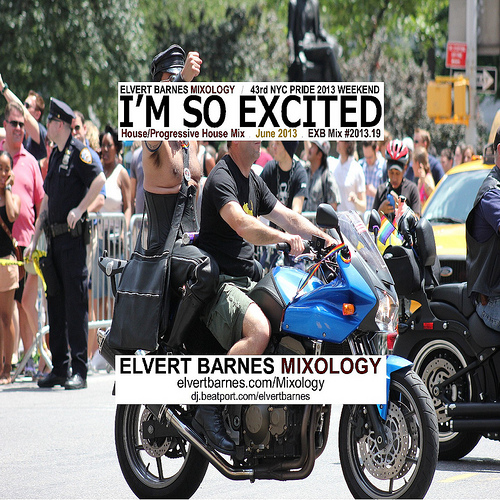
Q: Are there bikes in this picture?
A: Yes, there is a bike.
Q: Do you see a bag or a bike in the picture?
A: Yes, there is a bike.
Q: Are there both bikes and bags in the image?
A: Yes, there are both a bike and a bag.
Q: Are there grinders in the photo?
A: No, there are no grinders.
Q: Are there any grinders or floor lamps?
A: No, there are no grinders or floor lamps.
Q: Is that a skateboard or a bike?
A: That is a bike.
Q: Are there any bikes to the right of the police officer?
A: Yes, there is a bike to the right of the police officer.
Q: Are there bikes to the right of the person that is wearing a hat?
A: Yes, there is a bike to the right of the police officer.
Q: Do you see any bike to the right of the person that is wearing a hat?
A: Yes, there is a bike to the right of the police officer.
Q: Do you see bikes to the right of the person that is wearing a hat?
A: Yes, there is a bike to the right of the police officer.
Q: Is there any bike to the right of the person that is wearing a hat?
A: Yes, there is a bike to the right of the police officer.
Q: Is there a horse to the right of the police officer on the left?
A: No, there is a bike to the right of the police officer.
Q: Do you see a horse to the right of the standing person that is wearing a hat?
A: No, there is a bike to the right of the police officer.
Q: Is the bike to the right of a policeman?
A: Yes, the bike is to the right of a policeman.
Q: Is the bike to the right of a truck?
A: No, the bike is to the right of a policeman.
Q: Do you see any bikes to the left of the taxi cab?
A: Yes, there is a bike to the left of the taxi cab.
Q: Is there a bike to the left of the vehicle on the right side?
A: Yes, there is a bike to the left of the taxi cab.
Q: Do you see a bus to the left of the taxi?
A: No, there is a bike to the left of the taxi.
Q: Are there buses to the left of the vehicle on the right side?
A: No, there is a bike to the left of the taxi.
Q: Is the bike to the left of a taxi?
A: Yes, the bike is to the left of a taxi.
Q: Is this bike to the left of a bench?
A: No, the bike is to the left of a taxi.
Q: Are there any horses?
A: No, there are no horses.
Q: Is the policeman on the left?
A: Yes, the policeman is on the left of the image.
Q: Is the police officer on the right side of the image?
A: No, the police officer is on the left of the image.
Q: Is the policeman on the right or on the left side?
A: The policeman is on the left of the image.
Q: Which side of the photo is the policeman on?
A: The policeman is on the left of the image.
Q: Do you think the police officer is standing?
A: Yes, the police officer is standing.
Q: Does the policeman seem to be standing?
A: Yes, the policeman is standing.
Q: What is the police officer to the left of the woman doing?
A: The police officer is standing.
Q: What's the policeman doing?
A: The police officer is standing.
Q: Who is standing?
A: The police officer is standing.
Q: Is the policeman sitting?
A: No, the policeman is standing.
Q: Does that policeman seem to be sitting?
A: No, the policeman is standing.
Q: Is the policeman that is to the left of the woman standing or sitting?
A: The police officer is standing.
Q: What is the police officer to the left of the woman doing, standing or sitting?
A: The policeman is standing.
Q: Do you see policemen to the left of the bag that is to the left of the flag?
A: Yes, there is a policeman to the left of the bag.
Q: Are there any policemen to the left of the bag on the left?
A: Yes, there is a policeman to the left of the bag.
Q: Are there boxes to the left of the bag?
A: No, there is a policeman to the left of the bag.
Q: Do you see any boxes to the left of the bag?
A: No, there is a policeman to the left of the bag.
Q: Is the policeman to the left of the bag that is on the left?
A: Yes, the policeman is to the left of the bag.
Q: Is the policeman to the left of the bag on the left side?
A: Yes, the policeman is to the left of the bag.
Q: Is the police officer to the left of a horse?
A: No, the police officer is to the left of the bag.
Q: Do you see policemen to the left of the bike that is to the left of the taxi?
A: Yes, there is a policeman to the left of the bike.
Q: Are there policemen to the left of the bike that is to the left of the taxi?
A: Yes, there is a policeman to the left of the bike.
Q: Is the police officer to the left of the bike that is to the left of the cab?
A: Yes, the police officer is to the left of the bike.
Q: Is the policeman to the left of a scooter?
A: No, the policeman is to the left of the bike.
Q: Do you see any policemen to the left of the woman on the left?
A: Yes, there is a policeman to the left of the woman.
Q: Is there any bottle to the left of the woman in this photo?
A: No, there is a policeman to the left of the woman.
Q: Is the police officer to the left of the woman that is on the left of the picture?
A: Yes, the police officer is to the left of the woman.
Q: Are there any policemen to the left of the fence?
A: Yes, there is a policeman to the left of the fence.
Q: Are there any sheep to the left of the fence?
A: No, there is a policeman to the left of the fence.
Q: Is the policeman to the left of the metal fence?
A: Yes, the policeman is to the left of the fence.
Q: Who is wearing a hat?
A: The policeman is wearing a hat.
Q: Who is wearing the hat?
A: The policeman is wearing a hat.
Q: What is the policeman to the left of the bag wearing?
A: The policeman is wearing a hat.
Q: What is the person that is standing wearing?
A: The policeman is wearing a hat.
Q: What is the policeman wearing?
A: The policeman is wearing a hat.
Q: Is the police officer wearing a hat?
A: Yes, the police officer is wearing a hat.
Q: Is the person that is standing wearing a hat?
A: Yes, the police officer is wearing a hat.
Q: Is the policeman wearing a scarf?
A: No, the policeman is wearing a hat.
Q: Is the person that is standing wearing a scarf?
A: No, the policeman is wearing a hat.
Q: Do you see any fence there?
A: Yes, there is a fence.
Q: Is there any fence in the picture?
A: Yes, there is a fence.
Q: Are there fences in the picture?
A: Yes, there is a fence.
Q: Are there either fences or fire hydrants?
A: Yes, there is a fence.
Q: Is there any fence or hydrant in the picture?
A: Yes, there is a fence.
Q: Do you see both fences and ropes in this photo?
A: No, there is a fence but no ropes.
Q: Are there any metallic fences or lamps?
A: Yes, there is a metal fence.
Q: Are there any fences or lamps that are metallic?
A: Yes, the fence is metallic.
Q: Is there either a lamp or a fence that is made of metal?
A: Yes, the fence is made of metal.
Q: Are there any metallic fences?
A: Yes, there is a metal fence.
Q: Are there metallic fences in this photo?
A: Yes, there is a metal fence.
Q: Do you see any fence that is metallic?
A: Yes, there is a fence that is metallic.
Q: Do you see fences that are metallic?
A: Yes, there is a fence that is metallic.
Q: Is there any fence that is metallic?
A: Yes, there is a fence that is metallic.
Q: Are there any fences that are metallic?
A: Yes, there is a fence that is metallic.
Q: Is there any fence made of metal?
A: Yes, there is a fence that is made of metal.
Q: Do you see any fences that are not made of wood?
A: Yes, there is a fence that is made of metal.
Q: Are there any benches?
A: No, there are no benches.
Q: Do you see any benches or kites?
A: No, there are no benches or kites.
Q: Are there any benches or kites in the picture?
A: No, there are no benches or kites.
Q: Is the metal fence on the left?
A: Yes, the fence is on the left of the image.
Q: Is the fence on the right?
A: No, the fence is on the left of the image.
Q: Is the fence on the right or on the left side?
A: The fence is on the left of the image.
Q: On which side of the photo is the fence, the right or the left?
A: The fence is on the left of the image.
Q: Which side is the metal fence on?
A: The fence is on the left of the image.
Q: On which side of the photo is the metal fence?
A: The fence is on the left of the image.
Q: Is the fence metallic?
A: Yes, the fence is metallic.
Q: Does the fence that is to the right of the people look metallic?
A: Yes, the fence is metallic.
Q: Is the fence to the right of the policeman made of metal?
A: Yes, the fence is made of metal.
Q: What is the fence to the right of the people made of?
A: The fence is made of metal.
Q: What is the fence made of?
A: The fence is made of metal.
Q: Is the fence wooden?
A: No, the fence is metallic.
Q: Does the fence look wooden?
A: No, the fence is metallic.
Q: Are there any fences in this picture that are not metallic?
A: No, there is a fence but it is metallic.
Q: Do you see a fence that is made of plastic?
A: No, there is a fence but it is made of metal.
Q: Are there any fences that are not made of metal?
A: No, there is a fence but it is made of metal.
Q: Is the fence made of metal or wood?
A: The fence is made of metal.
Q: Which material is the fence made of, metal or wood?
A: The fence is made of metal.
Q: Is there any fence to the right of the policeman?
A: Yes, there is a fence to the right of the policeman.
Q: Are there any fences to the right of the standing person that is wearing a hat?
A: Yes, there is a fence to the right of the policeman.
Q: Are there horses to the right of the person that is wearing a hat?
A: No, there is a fence to the right of the police officer.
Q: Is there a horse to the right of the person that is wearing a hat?
A: No, there is a fence to the right of the police officer.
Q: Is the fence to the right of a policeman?
A: Yes, the fence is to the right of a policeman.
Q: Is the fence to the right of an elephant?
A: No, the fence is to the right of a policeman.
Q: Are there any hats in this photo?
A: Yes, there is a hat.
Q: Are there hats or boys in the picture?
A: Yes, there is a hat.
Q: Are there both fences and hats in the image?
A: Yes, there are both a hat and a fence.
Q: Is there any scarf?
A: No, there are no scarves.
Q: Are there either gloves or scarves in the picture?
A: No, there are no scarves or gloves.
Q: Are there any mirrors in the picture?
A: Yes, there is a mirror.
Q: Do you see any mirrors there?
A: Yes, there is a mirror.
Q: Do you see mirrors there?
A: Yes, there is a mirror.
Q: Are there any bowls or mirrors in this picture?
A: Yes, there is a mirror.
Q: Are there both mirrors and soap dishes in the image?
A: No, there is a mirror but no soap dishes.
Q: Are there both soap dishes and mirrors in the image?
A: No, there is a mirror but no soap dishes.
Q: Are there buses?
A: No, there are no buses.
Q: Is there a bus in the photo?
A: No, there are no buses.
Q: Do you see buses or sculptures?
A: No, there are no buses or sculptures.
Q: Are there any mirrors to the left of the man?
A: Yes, there is a mirror to the left of the man.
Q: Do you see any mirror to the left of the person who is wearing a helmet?
A: Yes, there is a mirror to the left of the man.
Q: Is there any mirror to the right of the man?
A: No, the mirror is to the left of the man.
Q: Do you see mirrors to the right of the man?
A: No, the mirror is to the left of the man.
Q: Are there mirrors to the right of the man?
A: No, the mirror is to the left of the man.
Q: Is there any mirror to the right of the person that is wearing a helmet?
A: No, the mirror is to the left of the man.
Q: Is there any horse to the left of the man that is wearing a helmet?
A: No, there is a mirror to the left of the man.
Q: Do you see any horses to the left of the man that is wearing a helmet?
A: No, there is a mirror to the left of the man.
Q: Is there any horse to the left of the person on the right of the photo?
A: No, there is a mirror to the left of the man.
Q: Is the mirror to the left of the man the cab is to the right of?
A: Yes, the mirror is to the left of the man.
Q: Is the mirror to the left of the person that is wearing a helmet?
A: Yes, the mirror is to the left of the man.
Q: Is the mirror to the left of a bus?
A: No, the mirror is to the left of the man.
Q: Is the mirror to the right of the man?
A: No, the mirror is to the left of the man.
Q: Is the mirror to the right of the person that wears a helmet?
A: No, the mirror is to the left of the man.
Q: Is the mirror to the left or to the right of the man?
A: The mirror is to the left of the man.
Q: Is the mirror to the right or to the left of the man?
A: The mirror is to the left of the man.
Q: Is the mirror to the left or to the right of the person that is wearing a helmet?
A: The mirror is to the left of the man.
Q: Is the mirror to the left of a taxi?
A: Yes, the mirror is to the left of a taxi.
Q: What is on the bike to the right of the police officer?
A: The mirror is on the bike.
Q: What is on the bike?
A: The mirror is on the bike.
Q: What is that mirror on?
A: The mirror is on the bike.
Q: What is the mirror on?
A: The mirror is on the bike.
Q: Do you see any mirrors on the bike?
A: Yes, there is a mirror on the bike.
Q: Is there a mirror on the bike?
A: Yes, there is a mirror on the bike.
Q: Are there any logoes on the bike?
A: No, there is a mirror on the bike.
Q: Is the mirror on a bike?
A: Yes, the mirror is on a bike.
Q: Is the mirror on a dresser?
A: No, the mirror is on a bike.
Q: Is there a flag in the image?
A: Yes, there is a flag.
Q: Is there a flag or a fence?
A: Yes, there is a flag.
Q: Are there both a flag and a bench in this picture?
A: No, there is a flag but no benches.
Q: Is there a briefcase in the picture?
A: No, there are no briefcases.